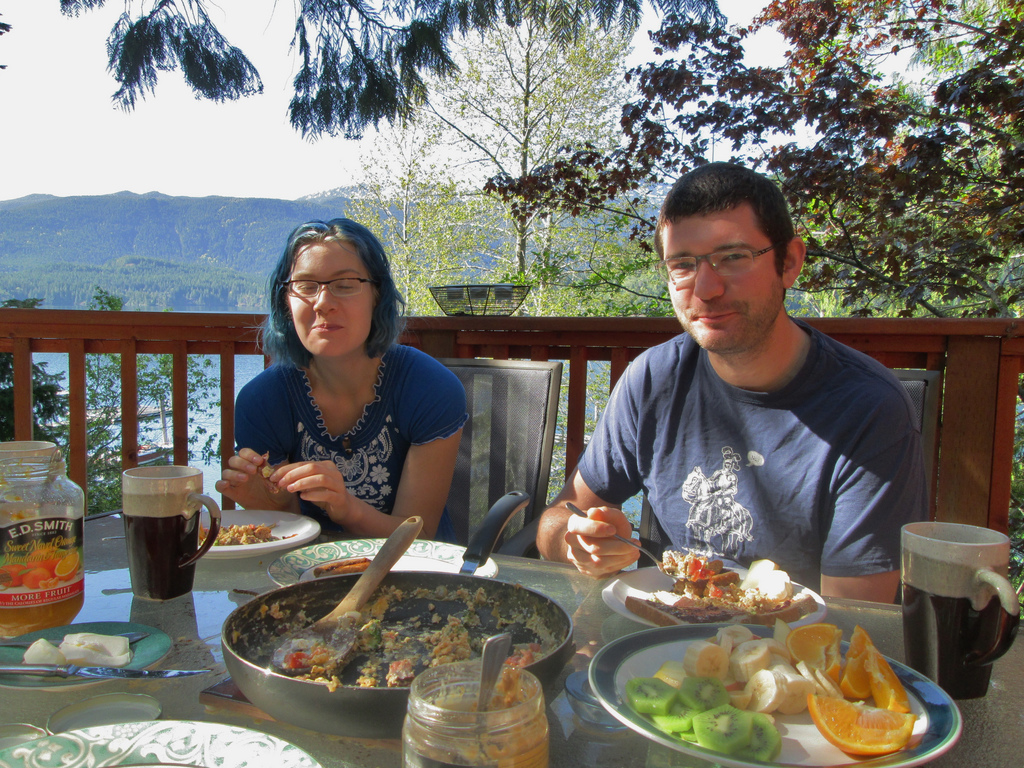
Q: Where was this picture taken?
A: Outdoors at a house by the lakeside.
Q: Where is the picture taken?
A: At a familiy meal.